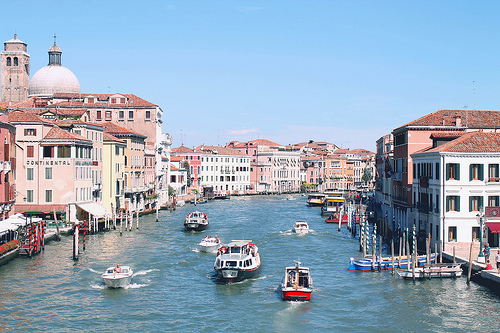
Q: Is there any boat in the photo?
A: Yes, there is a boat.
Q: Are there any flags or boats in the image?
A: Yes, there is a boat.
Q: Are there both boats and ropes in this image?
A: No, there is a boat but no ropes.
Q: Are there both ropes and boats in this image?
A: No, there is a boat but no ropes.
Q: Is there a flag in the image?
A: No, there are no flags.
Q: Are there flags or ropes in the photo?
A: No, there are no flags or ropes.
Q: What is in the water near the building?
A: The boat is in the water.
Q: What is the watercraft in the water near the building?
A: The watercraft is a boat.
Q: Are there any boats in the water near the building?
A: Yes, there is a boat in the water.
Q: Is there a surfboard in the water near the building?
A: No, there is a boat in the water.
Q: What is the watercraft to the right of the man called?
A: The watercraft is a boat.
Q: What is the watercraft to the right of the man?
A: The watercraft is a boat.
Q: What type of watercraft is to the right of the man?
A: The watercraft is a boat.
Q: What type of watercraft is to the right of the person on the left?
A: The watercraft is a boat.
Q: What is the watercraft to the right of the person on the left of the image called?
A: The watercraft is a boat.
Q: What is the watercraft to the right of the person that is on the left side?
A: The watercraft is a boat.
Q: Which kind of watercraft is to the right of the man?
A: The watercraft is a boat.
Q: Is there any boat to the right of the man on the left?
A: Yes, there is a boat to the right of the man.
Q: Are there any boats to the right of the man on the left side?
A: Yes, there is a boat to the right of the man.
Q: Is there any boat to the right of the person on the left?
A: Yes, there is a boat to the right of the man.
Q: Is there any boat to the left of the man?
A: No, the boat is to the right of the man.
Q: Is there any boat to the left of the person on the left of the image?
A: No, the boat is to the right of the man.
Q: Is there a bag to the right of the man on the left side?
A: No, there is a boat to the right of the man.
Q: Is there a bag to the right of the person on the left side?
A: No, there is a boat to the right of the man.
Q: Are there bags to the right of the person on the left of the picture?
A: No, there is a boat to the right of the man.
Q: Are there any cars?
A: No, there are no cars.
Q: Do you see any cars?
A: No, there are no cars.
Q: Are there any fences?
A: No, there are no fences.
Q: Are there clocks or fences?
A: No, there are no fences or clocks.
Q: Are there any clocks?
A: No, there are no clocks.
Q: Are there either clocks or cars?
A: No, there are no clocks or cars.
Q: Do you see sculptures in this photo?
A: No, there are no sculptures.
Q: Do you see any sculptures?
A: No, there are no sculptures.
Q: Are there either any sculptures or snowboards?
A: No, there are no sculptures or snowboards.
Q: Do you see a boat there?
A: Yes, there is a boat.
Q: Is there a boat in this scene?
A: Yes, there is a boat.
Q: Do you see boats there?
A: Yes, there is a boat.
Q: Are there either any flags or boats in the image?
A: Yes, there is a boat.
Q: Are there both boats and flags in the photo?
A: No, there is a boat but no flags.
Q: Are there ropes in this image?
A: No, there are no ropes.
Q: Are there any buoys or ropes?
A: No, there are no ropes or buoys.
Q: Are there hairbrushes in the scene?
A: No, there are no hairbrushes.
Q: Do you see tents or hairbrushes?
A: No, there are no hairbrushes or tents.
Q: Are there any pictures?
A: No, there are no pictures.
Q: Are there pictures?
A: No, there are no pictures.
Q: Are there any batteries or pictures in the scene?
A: No, there are no pictures or batteries.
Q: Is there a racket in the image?
A: No, there are no rackets.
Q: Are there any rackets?
A: No, there are no rackets.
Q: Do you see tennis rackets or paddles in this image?
A: No, there are no tennis rackets or paddles.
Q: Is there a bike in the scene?
A: No, there are no bikes.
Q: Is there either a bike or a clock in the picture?
A: No, there are no bikes or clocks.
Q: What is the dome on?
A: The dome is on the building.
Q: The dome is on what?
A: The dome is on the building.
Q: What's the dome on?
A: The dome is on the building.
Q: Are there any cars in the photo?
A: No, there are no cars.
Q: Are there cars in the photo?
A: No, there are no cars.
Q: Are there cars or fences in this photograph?
A: No, there are no cars or fences.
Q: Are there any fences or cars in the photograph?
A: No, there are no cars or fences.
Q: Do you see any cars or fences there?
A: No, there are no cars or fences.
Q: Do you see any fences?
A: No, there are no fences.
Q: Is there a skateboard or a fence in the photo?
A: No, there are no fences or skateboards.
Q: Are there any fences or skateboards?
A: No, there are no fences or skateboards.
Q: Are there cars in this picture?
A: No, there are no cars.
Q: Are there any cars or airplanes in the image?
A: No, there are no cars or airplanes.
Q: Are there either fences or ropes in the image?
A: No, there are no fences or ropes.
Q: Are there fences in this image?
A: No, there are no fences.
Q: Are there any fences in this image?
A: No, there are no fences.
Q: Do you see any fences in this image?
A: No, there are no fences.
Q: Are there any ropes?
A: No, there are no ropes.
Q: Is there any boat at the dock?
A: Yes, there are boats at the dock.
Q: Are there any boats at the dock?
A: Yes, there are boats at the dock.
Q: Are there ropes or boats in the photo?
A: Yes, there is a boat.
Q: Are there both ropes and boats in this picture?
A: No, there is a boat but no ropes.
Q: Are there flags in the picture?
A: No, there are no flags.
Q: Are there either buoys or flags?
A: No, there are no flags or buoys.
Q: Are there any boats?
A: Yes, there is a boat.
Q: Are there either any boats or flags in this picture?
A: Yes, there is a boat.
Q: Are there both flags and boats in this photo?
A: No, there is a boat but no flags.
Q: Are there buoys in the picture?
A: No, there are no buoys.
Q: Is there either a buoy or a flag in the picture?
A: No, there are no buoys or flags.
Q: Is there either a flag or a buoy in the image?
A: No, there are no buoys or flags.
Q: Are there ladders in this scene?
A: No, there are no ladders.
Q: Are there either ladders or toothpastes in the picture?
A: No, there are no ladders or toothpastes.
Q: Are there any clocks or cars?
A: No, there are no cars or clocks.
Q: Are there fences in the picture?
A: No, there are no fences.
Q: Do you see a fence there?
A: No, there are no fences.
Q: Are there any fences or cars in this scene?
A: No, there are no fences or cars.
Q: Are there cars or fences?
A: No, there are no fences or cars.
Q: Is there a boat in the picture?
A: Yes, there is a boat.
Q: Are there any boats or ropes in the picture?
A: Yes, there is a boat.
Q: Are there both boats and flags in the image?
A: No, there is a boat but no flags.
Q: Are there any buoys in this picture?
A: No, there are no buoys.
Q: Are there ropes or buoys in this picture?
A: No, there are no buoys or ropes.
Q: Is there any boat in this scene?
A: Yes, there is a boat.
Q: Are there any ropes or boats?
A: Yes, there is a boat.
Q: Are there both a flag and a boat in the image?
A: No, there is a boat but no flags.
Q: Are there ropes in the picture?
A: No, there are no ropes.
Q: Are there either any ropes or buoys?
A: No, there are no ropes or buoys.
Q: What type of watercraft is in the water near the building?
A: The watercraft is a boat.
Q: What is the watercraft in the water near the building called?
A: The watercraft is a boat.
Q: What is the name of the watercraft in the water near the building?
A: The watercraft is a boat.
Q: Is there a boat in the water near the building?
A: Yes, there is a boat in the water.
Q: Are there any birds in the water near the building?
A: No, there is a boat in the water.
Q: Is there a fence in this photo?
A: No, there are no fences.